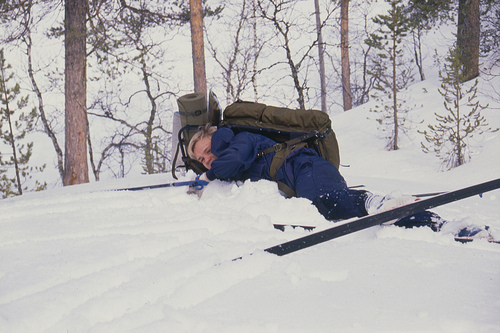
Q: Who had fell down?
A: Skier.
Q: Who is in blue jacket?
A: A man.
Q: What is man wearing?
A: Backpack.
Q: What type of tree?
A: Pine.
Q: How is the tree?
A: Young.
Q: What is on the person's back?
A: A backpack.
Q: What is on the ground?
A: Snow.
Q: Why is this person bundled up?
A: It's cold outside.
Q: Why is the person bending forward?
A: He fell down.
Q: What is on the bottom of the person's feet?
A: Skis.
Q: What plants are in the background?
A: Trees.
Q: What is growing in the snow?
A: Trees.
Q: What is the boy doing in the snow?
A: Skiing.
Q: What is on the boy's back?
A: A backpack.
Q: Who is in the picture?
A: A young boy.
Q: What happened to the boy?
A: He fell down.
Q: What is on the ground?
A: Snow.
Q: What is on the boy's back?
A: Backpack.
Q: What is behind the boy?
A: Trees.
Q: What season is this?
A: Winter.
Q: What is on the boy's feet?
A: Skis.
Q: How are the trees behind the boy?
A: Leafless.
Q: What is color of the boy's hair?
A: Blonde.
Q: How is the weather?
A: Cold.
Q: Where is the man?
A: On the ground.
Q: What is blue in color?
A: The man's jacket.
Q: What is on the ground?
A: Snow.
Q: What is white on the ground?
A: The snow.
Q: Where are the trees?
A: Alongside the hill.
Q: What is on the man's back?
A: A backpack.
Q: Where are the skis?
A: On the man's feet.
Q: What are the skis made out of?
A: Metal.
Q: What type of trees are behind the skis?
A: Saplings.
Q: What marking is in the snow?
A: Tracks.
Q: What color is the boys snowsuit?
A: Blue.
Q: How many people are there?
A: One.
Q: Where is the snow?
A: On the ground.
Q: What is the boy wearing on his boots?
A: Skis.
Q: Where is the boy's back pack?
A: On his back.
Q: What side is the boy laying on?
A: His right.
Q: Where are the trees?
A: Behind the boy.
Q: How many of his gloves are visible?
A: One.